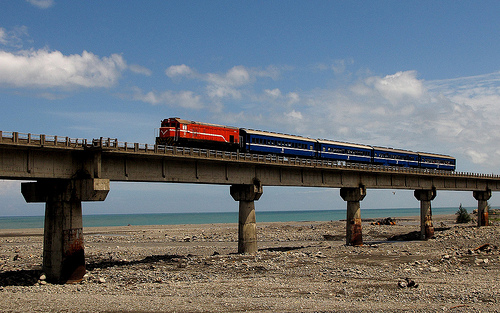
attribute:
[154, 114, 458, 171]
train — red, blue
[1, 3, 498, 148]
sky — blue, cloudy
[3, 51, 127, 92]
clouds — white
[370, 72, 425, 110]
clouds — white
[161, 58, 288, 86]
clouds — white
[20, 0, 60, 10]
clouds — white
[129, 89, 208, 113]
clouds — white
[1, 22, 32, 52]
clouds — white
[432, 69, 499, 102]
clouds — white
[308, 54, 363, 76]
clouds — white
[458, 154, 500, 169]
clouds — white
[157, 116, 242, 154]
car — red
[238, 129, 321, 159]
car — blue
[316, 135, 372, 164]
car — blue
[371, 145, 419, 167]
car — blue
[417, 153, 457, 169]
car — blue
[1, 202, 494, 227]
ocean — blue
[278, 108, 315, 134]
clouds — white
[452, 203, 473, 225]
shrub — green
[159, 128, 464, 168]
stripe — white